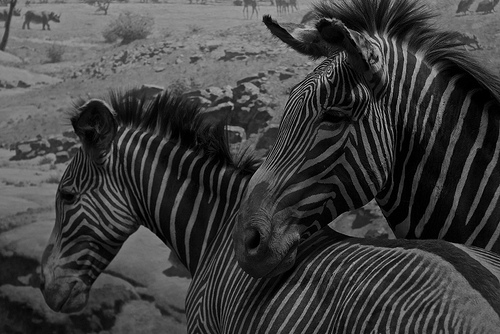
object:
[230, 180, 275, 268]
nose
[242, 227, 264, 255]
nostril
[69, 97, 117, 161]
ear zebra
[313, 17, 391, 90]
ear zebra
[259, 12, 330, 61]
ear zebra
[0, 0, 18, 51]
tree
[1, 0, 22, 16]
trunk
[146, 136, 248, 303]
stripes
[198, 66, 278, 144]
rocks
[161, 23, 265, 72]
ground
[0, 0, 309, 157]
field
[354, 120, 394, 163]
stripe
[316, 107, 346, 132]
eye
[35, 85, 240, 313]
white bag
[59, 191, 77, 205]
eye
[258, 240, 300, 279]
mouth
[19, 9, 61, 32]
animal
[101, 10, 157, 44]
bush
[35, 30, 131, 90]
ground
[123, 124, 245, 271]
neck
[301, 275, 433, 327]
stripes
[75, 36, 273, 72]
rocks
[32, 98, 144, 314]
animal's head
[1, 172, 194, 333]
flat rocks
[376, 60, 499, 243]
neck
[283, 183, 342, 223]
jaw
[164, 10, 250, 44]
background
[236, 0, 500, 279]
zebra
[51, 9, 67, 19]
corner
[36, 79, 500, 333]
zebra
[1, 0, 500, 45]
distance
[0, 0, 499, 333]
photo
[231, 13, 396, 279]
head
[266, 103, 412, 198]
stripes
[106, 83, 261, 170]
hairs